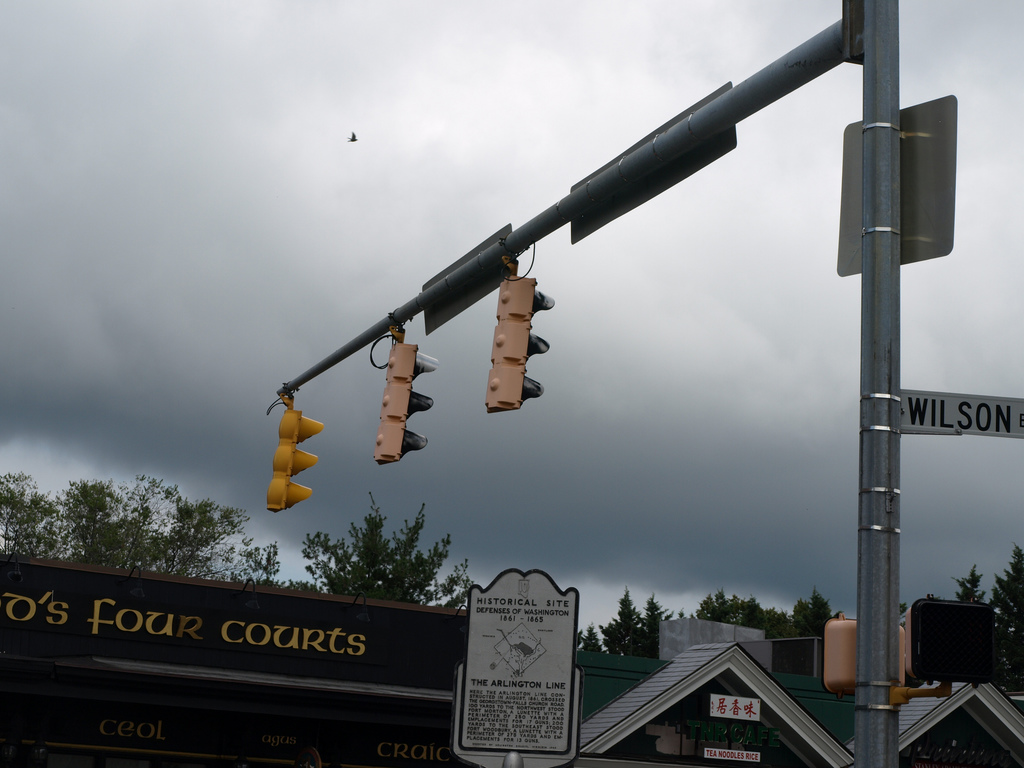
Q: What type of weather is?
A: It is cloudy.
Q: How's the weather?
A: It is cloudy.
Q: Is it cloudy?
A: Yes, it is cloudy.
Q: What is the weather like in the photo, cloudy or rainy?
A: It is cloudy.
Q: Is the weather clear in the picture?
A: No, it is cloudy.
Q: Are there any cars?
A: No, there are no cars.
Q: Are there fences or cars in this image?
A: No, there are no cars or fences.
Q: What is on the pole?
A: The sign is on the pole.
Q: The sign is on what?
A: The sign is on the pole.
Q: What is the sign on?
A: The sign is on the pole.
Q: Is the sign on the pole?
A: Yes, the sign is on the pole.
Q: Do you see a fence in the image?
A: No, there are no fences.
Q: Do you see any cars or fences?
A: No, there are no fences or cars.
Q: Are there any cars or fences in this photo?
A: No, there are no fences or cars.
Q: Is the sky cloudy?
A: Yes, the sky is cloudy.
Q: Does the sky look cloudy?
A: Yes, the sky is cloudy.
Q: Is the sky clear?
A: No, the sky is cloudy.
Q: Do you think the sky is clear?
A: No, the sky is cloudy.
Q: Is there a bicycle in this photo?
A: No, there are no bicycles.